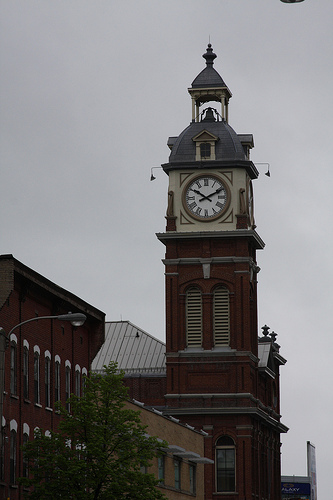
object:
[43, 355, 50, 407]
window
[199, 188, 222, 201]
black hands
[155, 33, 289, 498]
building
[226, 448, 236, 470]
window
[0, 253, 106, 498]
building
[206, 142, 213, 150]
window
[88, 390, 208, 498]
building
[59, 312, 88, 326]
light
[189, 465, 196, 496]
window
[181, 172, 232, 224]
clock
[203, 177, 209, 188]
numbers